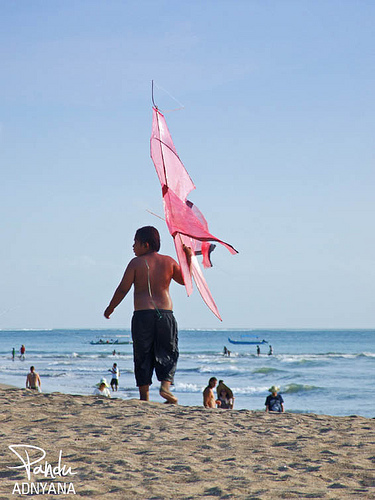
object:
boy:
[103, 224, 193, 405]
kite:
[142, 77, 242, 323]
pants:
[130, 309, 181, 388]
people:
[201, 376, 222, 411]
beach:
[0, 382, 374, 498]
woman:
[215, 387, 235, 410]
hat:
[216, 379, 234, 399]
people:
[222, 345, 228, 356]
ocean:
[0, 329, 375, 418]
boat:
[226, 336, 268, 346]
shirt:
[216, 396, 231, 410]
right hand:
[182, 243, 192, 258]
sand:
[172, 474, 202, 500]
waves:
[52, 357, 90, 375]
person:
[92, 377, 111, 398]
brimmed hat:
[94, 377, 111, 387]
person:
[264, 386, 285, 414]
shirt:
[264, 393, 285, 412]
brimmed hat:
[267, 385, 280, 394]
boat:
[87, 335, 131, 349]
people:
[98, 338, 103, 344]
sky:
[0, 0, 375, 329]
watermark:
[6, 439, 77, 499]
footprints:
[98, 454, 192, 486]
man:
[24, 365, 42, 394]